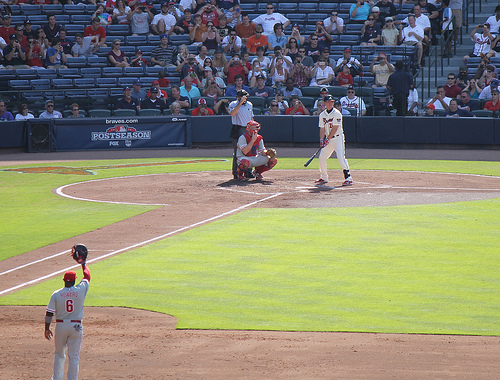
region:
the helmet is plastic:
[225, 72, 290, 164]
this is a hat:
[48, 264, 88, 292]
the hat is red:
[58, 244, 145, 301]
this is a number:
[62, 276, 113, 373]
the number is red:
[67, 269, 88, 337]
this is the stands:
[94, 66, 214, 176]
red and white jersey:
[46, 282, 89, 325]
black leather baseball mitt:
[70, 242, 88, 265]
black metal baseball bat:
[306, 143, 326, 168]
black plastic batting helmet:
[323, 94, 334, 101]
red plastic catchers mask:
[246, 120, 258, 135]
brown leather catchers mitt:
[264, 149, 276, 159]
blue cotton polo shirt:
[227, 100, 254, 127]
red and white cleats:
[313, 177, 326, 186]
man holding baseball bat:
[305, 95, 354, 187]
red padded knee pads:
[236, 160, 277, 181]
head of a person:
[320, 85, 342, 116]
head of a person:
[60, 268, 80, 295]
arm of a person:
[66, 246, 104, 290]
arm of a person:
[37, 299, 51, 344]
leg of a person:
[46, 332, 68, 379]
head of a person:
[319, 92, 341, 113]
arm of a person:
[322, 118, 344, 140]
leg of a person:
[330, 151, 360, 182]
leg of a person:
[312, 153, 336, 181]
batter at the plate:
[293, 80, 387, 188]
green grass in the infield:
[258, 225, 379, 310]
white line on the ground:
[153, 202, 243, 259]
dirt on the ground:
[156, 330, 249, 379]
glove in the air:
[61, 233, 103, 268]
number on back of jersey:
[52, 287, 83, 324]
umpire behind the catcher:
[220, 84, 263, 124]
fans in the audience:
[129, 14, 344, 104]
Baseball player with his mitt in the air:
[44, 242, 91, 379]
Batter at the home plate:
[304, 92, 355, 189]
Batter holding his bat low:
[300, 90, 352, 190]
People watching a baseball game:
[0, 0, 498, 123]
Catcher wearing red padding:
[232, 118, 277, 183]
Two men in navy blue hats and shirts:
[115, 81, 165, 113]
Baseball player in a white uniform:
[304, 93, 354, 188]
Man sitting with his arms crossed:
[165, 82, 191, 108]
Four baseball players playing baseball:
[42, 86, 355, 378]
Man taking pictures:
[368, 53, 395, 88]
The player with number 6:
[39, 245, 117, 372]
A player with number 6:
[36, 237, 136, 374]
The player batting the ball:
[299, 83, 367, 187]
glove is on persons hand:
[71, 240, 106, 274]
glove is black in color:
[64, 238, 90, 265]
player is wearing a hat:
[64, 268, 81, 283]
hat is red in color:
[56, 256, 79, 283]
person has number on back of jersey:
[60, 289, 85, 319]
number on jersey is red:
[59, 299, 79, 317]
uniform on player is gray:
[39, 265, 94, 330]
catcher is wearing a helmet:
[241, 116, 265, 131]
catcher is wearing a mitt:
[263, 143, 278, 158]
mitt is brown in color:
[257, 143, 279, 162]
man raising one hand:
[32, 231, 111, 376]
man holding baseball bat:
[291, 92, 357, 199]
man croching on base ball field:
[233, 117, 288, 202]